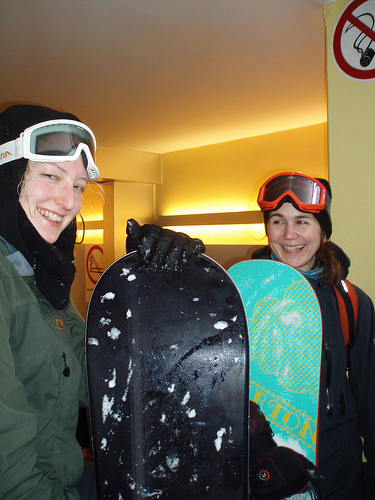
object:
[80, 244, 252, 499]
snowboard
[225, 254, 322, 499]
snowboard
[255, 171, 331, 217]
goggles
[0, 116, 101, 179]
goggles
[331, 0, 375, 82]
sign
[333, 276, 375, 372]
backpack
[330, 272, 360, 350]
strap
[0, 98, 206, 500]
women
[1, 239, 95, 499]
jacket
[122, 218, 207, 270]
gloves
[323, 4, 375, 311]
wall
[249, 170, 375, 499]
woman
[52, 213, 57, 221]
teeth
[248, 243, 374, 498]
skiing suit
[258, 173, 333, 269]
head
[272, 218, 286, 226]
eye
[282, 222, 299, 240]
nose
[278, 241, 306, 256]
mouth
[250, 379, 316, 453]
writing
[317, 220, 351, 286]
hair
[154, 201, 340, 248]
lights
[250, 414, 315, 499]
glove